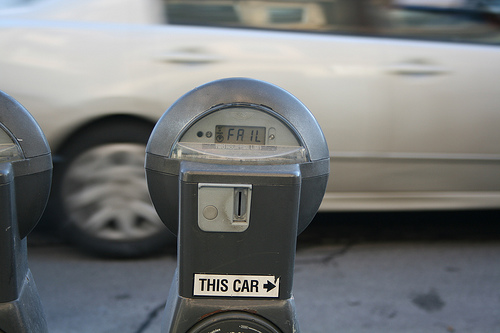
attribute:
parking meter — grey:
[145, 82, 333, 322]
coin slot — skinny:
[230, 189, 252, 228]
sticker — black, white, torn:
[197, 271, 279, 301]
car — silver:
[5, 6, 492, 243]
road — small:
[370, 249, 464, 305]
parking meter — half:
[3, 97, 72, 299]